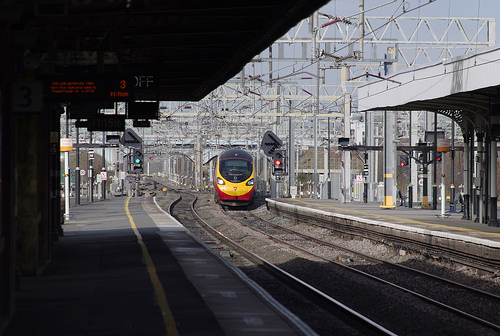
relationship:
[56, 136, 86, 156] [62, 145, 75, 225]
sign on post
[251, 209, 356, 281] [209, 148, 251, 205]
tracks for train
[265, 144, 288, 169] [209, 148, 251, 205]
light for train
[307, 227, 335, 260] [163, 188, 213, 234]
gravel on track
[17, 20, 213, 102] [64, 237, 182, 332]
building gives shade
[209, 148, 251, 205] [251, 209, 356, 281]
train on tracks